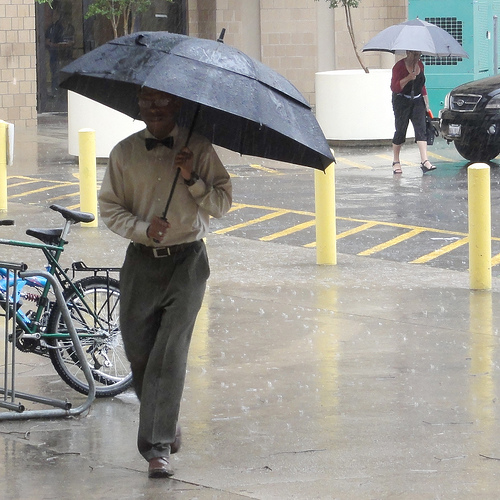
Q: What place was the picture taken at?
A: It was taken at the sidewalk.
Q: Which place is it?
A: It is a sidewalk.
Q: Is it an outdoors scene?
A: Yes, it is outdoors.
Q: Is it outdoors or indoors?
A: It is outdoors.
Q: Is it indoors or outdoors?
A: It is outdoors.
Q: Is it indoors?
A: No, it is outdoors.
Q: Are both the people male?
A: No, they are both male and female.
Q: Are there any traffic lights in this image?
A: No, there are no traffic lights.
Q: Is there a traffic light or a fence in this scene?
A: No, there are no traffic lights or fences.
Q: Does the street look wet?
A: Yes, the street is wet.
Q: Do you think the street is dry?
A: No, the street is wet.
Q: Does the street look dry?
A: No, the street is wet.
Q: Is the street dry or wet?
A: The street is wet.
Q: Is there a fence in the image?
A: No, there are no fences.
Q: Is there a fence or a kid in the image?
A: No, there are no fences or children.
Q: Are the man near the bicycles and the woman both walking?
A: Yes, both the man and the woman are walking.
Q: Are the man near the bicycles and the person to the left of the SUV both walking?
A: Yes, both the man and the woman are walking.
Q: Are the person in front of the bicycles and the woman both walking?
A: Yes, both the man and the woman are walking.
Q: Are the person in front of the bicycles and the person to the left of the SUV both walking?
A: Yes, both the man and the woman are walking.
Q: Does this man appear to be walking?
A: Yes, the man is walking.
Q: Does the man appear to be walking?
A: Yes, the man is walking.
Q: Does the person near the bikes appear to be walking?
A: Yes, the man is walking.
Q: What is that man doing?
A: The man is walking.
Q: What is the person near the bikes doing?
A: The man is walking.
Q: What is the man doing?
A: The man is walking.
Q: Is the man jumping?
A: No, the man is walking.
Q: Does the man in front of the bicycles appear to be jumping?
A: No, the man is walking.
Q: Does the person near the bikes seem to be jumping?
A: No, the man is walking.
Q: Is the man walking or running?
A: The man is walking.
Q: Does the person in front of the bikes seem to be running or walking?
A: The man is walking.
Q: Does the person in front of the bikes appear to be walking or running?
A: The man is walking.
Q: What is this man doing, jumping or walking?
A: The man is walking.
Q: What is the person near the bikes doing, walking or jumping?
A: The man is walking.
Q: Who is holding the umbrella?
A: The man is holding the umbrella.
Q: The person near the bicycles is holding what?
A: The man is holding the umbrella.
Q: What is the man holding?
A: The man is holding the umbrella.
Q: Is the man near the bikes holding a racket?
A: No, the man is holding the umbrella.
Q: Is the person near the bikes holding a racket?
A: No, the man is holding the umbrella.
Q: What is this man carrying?
A: The man is carrying an umbrella.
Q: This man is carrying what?
A: The man is carrying an umbrella.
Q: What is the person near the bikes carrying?
A: The man is carrying an umbrella.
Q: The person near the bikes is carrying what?
A: The man is carrying an umbrella.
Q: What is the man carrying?
A: The man is carrying an umbrella.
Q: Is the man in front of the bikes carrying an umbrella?
A: Yes, the man is carrying an umbrella.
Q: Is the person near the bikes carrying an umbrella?
A: Yes, the man is carrying an umbrella.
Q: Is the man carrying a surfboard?
A: No, the man is carrying an umbrella.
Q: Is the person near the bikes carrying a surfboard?
A: No, the man is carrying an umbrella.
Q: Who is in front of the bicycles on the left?
A: The man is in front of the bicycles.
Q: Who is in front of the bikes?
A: The man is in front of the bicycles.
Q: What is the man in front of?
A: The man is in front of the bicycles.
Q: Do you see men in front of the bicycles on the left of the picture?
A: Yes, there is a man in front of the bicycles.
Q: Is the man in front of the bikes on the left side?
A: Yes, the man is in front of the bicycles.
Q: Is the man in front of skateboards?
A: No, the man is in front of the bicycles.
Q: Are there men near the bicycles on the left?
A: Yes, there is a man near the bikes.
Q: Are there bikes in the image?
A: Yes, there are bikes.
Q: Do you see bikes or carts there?
A: Yes, there are bikes.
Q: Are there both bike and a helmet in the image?
A: No, there are bikes but no helmets.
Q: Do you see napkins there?
A: No, there are no napkins.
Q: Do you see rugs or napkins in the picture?
A: No, there are no napkins or rugs.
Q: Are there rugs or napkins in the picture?
A: No, there are no napkins or rugs.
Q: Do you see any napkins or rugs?
A: No, there are no napkins or rugs.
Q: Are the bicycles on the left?
A: Yes, the bicycles are on the left of the image.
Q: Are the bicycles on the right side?
A: No, the bicycles are on the left of the image.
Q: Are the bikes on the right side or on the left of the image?
A: The bikes are on the left of the image.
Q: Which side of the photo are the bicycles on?
A: The bicycles are on the left of the image.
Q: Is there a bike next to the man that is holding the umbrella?
A: Yes, there are bikes next to the man.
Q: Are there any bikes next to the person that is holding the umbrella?
A: Yes, there are bikes next to the man.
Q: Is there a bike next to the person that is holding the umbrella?
A: Yes, there are bikes next to the man.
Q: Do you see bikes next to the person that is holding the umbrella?
A: Yes, there are bikes next to the man.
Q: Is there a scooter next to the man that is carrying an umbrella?
A: No, there are bikes next to the man.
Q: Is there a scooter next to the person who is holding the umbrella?
A: No, there are bikes next to the man.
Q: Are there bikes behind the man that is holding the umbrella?
A: Yes, there are bikes behind the man.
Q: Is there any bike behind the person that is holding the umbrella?
A: Yes, there are bikes behind the man.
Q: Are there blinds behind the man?
A: No, there are bikes behind the man.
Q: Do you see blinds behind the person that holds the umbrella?
A: No, there are bikes behind the man.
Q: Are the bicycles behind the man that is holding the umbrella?
A: Yes, the bicycles are behind the man.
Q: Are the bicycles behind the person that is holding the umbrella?
A: Yes, the bicycles are behind the man.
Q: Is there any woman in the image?
A: Yes, there is a woman.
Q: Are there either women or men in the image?
A: Yes, there is a woman.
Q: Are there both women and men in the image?
A: Yes, there are both a woman and a man.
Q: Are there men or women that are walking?
A: Yes, the woman is walking.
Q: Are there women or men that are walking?
A: Yes, the woman is walking.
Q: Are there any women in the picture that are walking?
A: Yes, there is a woman that is walking.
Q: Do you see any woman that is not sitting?
A: Yes, there is a woman that is walking .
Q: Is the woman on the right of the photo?
A: Yes, the woman is on the right of the image.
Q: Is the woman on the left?
A: No, the woman is on the right of the image.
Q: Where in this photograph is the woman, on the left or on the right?
A: The woman is on the right of the image.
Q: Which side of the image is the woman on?
A: The woman is on the right of the image.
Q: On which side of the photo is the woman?
A: The woman is on the right of the image.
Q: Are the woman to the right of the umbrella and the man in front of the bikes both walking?
A: Yes, both the woman and the man are walking.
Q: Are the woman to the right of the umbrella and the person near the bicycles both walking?
A: Yes, both the woman and the man are walking.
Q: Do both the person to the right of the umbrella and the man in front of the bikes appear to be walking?
A: Yes, both the woman and the man are walking.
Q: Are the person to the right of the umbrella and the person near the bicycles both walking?
A: Yes, both the woman and the man are walking.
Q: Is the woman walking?
A: Yes, the woman is walking.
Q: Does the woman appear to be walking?
A: Yes, the woman is walking.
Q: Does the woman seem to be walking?
A: Yes, the woman is walking.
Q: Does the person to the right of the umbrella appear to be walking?
A: Yes, the woman is walking.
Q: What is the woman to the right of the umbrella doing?
A: The woman is walking.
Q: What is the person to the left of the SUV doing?
A: The woman is walking.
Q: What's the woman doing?
A: The woman is walking.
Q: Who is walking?
A: The woman is walking.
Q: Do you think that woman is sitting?
A: No, the woman is walking.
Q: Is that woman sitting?
A: No, the woman is walking.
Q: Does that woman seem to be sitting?
A: No, the woman is walking.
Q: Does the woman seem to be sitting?
A: No, the woman is walking.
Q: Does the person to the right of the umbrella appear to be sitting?
A: No, the woman is walking.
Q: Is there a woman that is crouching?
A: No, there is a woman but she is walking.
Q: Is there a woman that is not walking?
A: No, there is a woman but she is walking.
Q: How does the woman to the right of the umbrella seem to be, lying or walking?
A: The woman is walking.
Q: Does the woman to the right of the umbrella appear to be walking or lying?
A: The woman is walking.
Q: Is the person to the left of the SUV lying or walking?
A: The woman is walking.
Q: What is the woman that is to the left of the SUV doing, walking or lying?
A: The woman is walking.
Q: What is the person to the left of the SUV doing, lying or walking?
A: The woman is walking.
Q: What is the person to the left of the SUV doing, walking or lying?
A: The woman is walking.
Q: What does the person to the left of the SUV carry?
A: The woman carries an umbrella.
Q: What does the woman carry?
A: The woman carries an umbrella.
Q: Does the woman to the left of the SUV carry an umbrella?
A: Yes, the woman carries an umbrella.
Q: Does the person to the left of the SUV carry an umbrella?
A: Yes, the woman carries an umbrella.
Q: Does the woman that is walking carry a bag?
A: No, the woman carries an umbrella.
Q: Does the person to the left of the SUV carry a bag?
A: No, the woman carries an umbrella.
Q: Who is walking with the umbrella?
A: The woman is walking with the umbrella.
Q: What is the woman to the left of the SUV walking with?
A: The woman is walking with an umbrella.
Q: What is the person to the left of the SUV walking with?
A: The woman is walking with an umbrella.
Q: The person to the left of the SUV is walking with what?
A: The woman is walking with an umbrella.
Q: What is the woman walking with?
A: The woman is walking with an umbrella.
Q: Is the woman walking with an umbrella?
A: Yes, the woman is walking with an umbrella.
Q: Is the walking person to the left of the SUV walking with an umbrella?
A: Yes, the woman is walking with an umbrella.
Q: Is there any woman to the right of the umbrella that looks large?
A: Yes, there is a woman to the right of the umbrella.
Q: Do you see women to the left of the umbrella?
A: No, the woman is to the right of the umbrella.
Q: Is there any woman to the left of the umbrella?
A: No, the woman is to the right of the umbrella.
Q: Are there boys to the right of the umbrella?
A: No, there is a woman to the right of the umbrella.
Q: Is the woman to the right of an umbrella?
A: Yes, the woman is to the right of an umbrella.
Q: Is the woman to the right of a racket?
A: No, the woman is to the right of an umbrella.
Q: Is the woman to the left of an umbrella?
A: No, the woman is to the right of an umbrella.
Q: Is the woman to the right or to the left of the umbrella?
A: The woman is to the right of the umbrella.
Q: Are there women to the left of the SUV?
A: Yes, there is a woman to the left of the SUV.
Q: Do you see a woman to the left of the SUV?
A: Yes, there is a woman to the left of the SUV.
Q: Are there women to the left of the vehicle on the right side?
A: Yes, there is a woman to the left of the SUV.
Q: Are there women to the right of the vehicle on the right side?
A: No, the woman is to the left of the SUV.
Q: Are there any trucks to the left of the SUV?
A: No, there is a woman to the left of the SUV.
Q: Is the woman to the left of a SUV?
A: Yes, the woman is to the left of a SUV.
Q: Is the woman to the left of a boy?
A: No, the woman is to the left of a SUV.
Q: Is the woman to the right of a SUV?
A: No, the woman is to the left of a SUV.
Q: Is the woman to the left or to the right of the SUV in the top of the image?
A: The woman is to the left of the SUV.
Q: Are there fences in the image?
A: No, there are no fences.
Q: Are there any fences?
A: No, there are no fences.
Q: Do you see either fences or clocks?
A: No, there are no fences or clocks.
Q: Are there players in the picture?
A: No, there are no players.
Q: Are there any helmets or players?
A: No, there are no players or helmets.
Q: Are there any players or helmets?
A: No, there are no players or helmets.